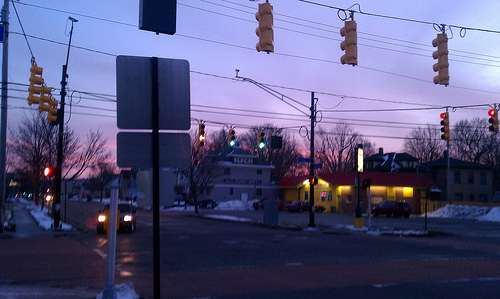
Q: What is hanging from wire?
A: Lights.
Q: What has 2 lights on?
A: Car.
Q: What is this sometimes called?
A: Intersection.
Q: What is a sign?
A: The rectangles.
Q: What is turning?
A: A car.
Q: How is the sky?
A: Pink, gray and blue.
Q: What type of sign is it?
A: A street sign.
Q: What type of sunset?
A: Pink and blue.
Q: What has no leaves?
A: The trees.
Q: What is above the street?
A: The wires.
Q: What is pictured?
A: Traffic intersection.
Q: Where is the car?
A: On the road.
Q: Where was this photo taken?
A: On a street corner.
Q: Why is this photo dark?
A: It's night time.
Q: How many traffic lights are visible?
A: 11.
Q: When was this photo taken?
A: During the winter months.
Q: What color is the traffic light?
A: Red.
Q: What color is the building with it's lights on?
A: Yellow.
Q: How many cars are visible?
A: One.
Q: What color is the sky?
A: Blue and purple.